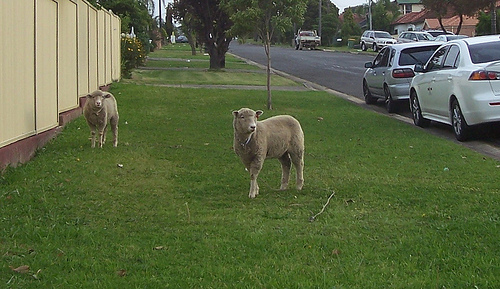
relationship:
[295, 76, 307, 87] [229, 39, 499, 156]
curb along street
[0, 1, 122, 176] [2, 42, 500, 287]
wall next to grass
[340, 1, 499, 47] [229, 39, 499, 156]
houses along street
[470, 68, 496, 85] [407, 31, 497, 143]
lights on car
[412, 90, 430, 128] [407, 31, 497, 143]
tire on car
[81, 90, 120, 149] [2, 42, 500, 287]
sheep on grass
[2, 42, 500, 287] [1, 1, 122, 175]
grass near fence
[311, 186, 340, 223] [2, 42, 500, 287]
stick on grass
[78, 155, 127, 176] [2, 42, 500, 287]
leaves on grass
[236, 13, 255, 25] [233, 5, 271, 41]
leaves has branches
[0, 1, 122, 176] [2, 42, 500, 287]
wall by grass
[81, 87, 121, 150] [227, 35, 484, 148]
sheep standing on side of road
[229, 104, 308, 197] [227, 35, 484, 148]
sheep standing on side of road